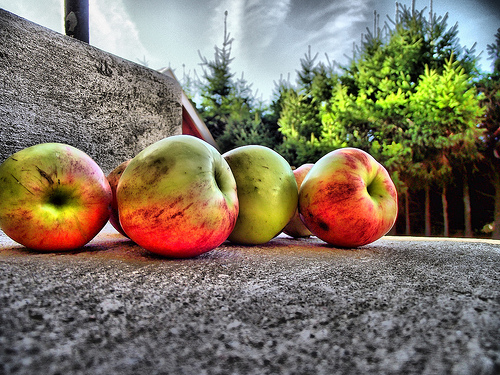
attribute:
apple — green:
[221, 145, 298, 246]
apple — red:
[299, 148, 398, 246]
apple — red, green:
[116, 135, 240, 260]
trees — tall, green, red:
[181, 1, 498, 241]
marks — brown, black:
[116, 156, 179, 206]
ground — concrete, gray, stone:
[0, 237, 498, 372]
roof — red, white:
[162, 65, 224, 153]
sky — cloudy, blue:
[1, 2, 496, 113]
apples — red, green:
[0, 133, 399, 258]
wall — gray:
[1, 6, 184, 180]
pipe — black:
[65, 0, 89, 46]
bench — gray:
[3, 6, 500, 374]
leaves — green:
[181, 3, 499, 191]